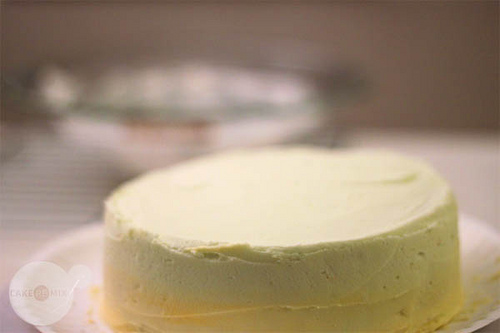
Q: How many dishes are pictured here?
A: Two.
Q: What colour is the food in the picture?
A: White and yellow.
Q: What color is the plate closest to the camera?
A: White.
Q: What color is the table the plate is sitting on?
A: White.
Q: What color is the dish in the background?
A: Silver.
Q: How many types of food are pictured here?
A: One.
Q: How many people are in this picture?
A: Zero.